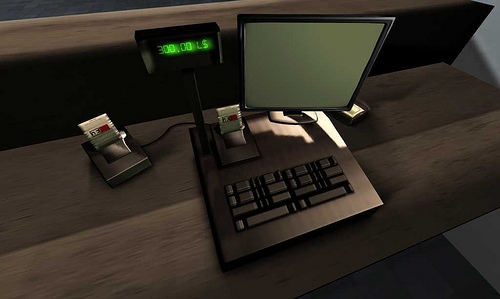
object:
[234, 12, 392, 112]
moniter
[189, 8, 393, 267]
computers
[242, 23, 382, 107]
screen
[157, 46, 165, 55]
letters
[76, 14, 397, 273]
register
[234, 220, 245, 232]
buttons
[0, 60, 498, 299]
counter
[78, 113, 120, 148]
paper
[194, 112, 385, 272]
base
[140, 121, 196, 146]
cord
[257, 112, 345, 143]
light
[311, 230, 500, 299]
floor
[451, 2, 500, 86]
wall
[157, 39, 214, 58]
screen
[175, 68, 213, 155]
pole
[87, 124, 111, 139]
timer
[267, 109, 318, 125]
stand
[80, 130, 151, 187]
box